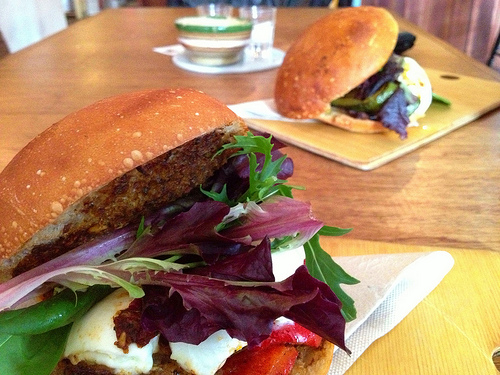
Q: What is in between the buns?
A: Vegetables.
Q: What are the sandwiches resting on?
A: Planks of wood.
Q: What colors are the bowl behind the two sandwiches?
A: Green, tan, and white.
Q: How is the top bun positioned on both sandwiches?
A: At an angle.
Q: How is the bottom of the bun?
A: Browned.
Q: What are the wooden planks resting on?
A: A wooden table.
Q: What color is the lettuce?
A: Purple.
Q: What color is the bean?
A: Green.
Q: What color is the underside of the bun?
A: Brown.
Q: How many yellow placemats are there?
A: Two.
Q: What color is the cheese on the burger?
A: White.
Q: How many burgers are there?
A: Two.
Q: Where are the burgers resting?
A: On a table.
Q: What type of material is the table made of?
A: Wood.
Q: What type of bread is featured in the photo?
A: Buns.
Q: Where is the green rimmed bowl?
A: Behind the burgers.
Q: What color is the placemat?
A: Yellow.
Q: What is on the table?
A: A burger.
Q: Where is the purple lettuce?
A: On the burger.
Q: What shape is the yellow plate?
A: Rectangular.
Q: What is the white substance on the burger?
A: Melted cheese.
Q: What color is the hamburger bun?
A: Brown.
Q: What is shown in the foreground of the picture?
A: A hamburger filled with fixings.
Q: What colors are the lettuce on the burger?
A: Green and purple.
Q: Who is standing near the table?
A: No one.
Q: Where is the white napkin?
A: Underneath a hamburger.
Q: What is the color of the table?
A: Light brown.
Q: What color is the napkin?
A: White.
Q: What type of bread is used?
A: Buns.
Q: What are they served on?
A: Bamboo servers.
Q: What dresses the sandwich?
A: Colorful leafy veggies.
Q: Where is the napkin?
A: Under the sandwich.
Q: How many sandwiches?
A: 2.